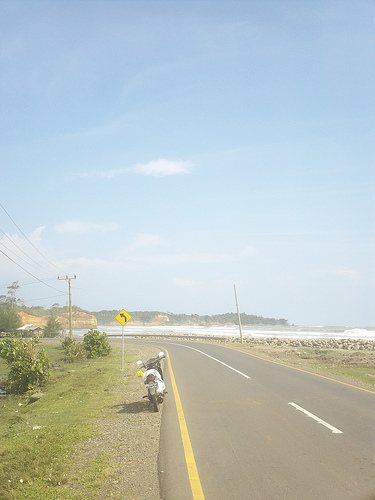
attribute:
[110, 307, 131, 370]
sign — yellow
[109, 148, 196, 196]
cloud — white, faint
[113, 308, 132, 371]
signpost — gray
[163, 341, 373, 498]
highway —  blacktop,  short stretch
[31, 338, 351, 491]
road — asphalt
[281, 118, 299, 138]
ground — leafy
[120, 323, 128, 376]
pole — metal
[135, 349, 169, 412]
motorbike —  parked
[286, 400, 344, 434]
line — white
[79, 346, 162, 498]
shouler — gravel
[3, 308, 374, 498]
landscape — grassy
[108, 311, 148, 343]
arrow — black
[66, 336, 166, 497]
shoulder — dirt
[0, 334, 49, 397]
bush — bent